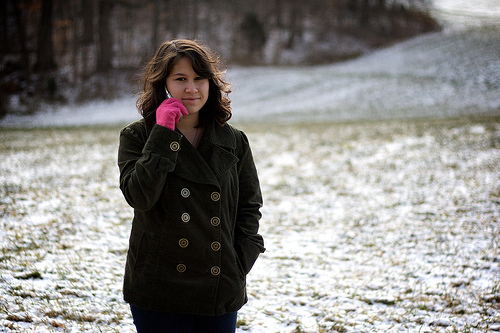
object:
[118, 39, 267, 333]
woman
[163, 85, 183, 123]
phone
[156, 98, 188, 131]
glove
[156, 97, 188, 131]
hand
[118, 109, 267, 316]
coat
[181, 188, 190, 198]
button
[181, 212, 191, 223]
button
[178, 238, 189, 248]
button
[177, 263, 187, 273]
button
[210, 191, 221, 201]
button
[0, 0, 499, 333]
grass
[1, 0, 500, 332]
snow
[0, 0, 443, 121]
wooded area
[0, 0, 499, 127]
hillside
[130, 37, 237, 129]
hair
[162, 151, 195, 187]
right lapel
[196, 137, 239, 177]
left lapel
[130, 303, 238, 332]
jeans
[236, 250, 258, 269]
left hand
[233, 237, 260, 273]
pocket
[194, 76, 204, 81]
left eye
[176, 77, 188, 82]
right eye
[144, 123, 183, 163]
cuff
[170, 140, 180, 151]
button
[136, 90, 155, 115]
curl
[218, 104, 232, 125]
curl